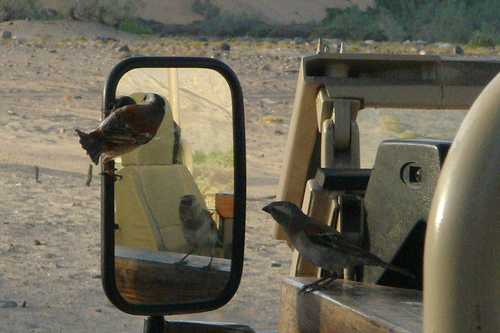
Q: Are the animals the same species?
A: Yes, all the animals are birds.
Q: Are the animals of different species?
A: No, all the animals are birds.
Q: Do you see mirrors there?
A: Yes, there is a mirror.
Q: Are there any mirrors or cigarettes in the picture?
A: Yes, there is a mirror.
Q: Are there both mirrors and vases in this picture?
A: No, there is a mirror but no vases.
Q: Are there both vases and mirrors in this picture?
A: No, there is a mirror but no vases.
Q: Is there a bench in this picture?
A: No, there are no benches.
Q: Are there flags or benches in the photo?
A: No, there are no benches or flags.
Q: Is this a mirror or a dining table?
A: This is a mirror.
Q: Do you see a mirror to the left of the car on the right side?
A: Yes, there is a mirror to the left of the car.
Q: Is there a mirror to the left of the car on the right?
A: Yes, there is a mirror to the left of the car.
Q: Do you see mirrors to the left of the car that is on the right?
A: Yes, there is a mirror to the left of the car.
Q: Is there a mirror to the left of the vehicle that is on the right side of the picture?
A: Yes, there is a mirror to the left of the car.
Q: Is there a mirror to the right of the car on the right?
A: No, the mirror is to the left of the car.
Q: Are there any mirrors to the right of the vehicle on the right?
A: No, the mirror is to the left of the car.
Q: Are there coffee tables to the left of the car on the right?
A: No, there is a mirror to the left of the car.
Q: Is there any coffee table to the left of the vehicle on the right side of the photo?
A: No, there is a mirror to the left of the car.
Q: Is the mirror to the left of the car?
A: Yes, the mirror is to the left of the car.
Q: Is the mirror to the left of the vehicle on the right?
A: Yes, the mirror is to the left of the car.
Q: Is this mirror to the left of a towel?
A: No, the mirror is to the left of the car.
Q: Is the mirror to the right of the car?
A: No, the mirror is to the left of the car.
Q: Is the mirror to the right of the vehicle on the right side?
A: No, the mirror is to the left of the car.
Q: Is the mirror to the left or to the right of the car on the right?
A: The mirror is to the left of the car.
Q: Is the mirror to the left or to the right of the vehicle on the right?
A: The mirror is to the left of the car.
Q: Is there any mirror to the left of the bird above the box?
A: Yes, there is a mirror to the left of the bird.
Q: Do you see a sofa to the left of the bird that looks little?
A: No, there is a mirror to the left of the bird.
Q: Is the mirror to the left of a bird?
A: Yes, the mirror is to the left of a bird.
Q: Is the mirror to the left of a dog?
A: No, the mirror is to the left of a bird.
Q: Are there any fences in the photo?
A: No, there are no fences.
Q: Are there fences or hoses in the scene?
A: No, there are no fences or hoses.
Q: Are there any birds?
A: Yes, there is a bird.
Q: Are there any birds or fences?
A: Yes, there is a bird.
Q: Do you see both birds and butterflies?
A: No, there is a bird but no butterflies.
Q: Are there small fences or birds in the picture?
A: Yes, there is a small bird.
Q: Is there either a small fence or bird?
A: Yes, there is a small bird.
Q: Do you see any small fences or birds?
A: Yes, there is a small bird.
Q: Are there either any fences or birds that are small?
A: Yes, the bird is small.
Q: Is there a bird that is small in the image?
A: Yes, there is a small bird.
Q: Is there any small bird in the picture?
A: Yes, there is a small bird.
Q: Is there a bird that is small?
A: Yes, there is a bird that is small.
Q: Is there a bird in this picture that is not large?
A: Yes, there is a small bird.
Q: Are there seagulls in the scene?
A: No, there are no seagulls.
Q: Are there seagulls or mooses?
A: No, there are no seagulls or mooses.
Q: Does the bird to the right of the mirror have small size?
A: Yes, the bird is small.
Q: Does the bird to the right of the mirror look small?
A: Yes, the bird is small.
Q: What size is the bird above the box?
A: The bird is small.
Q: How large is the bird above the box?
A: The bird is small.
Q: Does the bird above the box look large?
A: No, the bird is small.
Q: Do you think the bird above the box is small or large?
A: The bird is small.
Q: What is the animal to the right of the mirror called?
A: The animal is a bird.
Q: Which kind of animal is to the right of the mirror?
A: The animal is a bird.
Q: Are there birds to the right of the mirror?
A: Yes, there is a bird to the right of the mirror.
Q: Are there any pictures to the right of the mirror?
A: No, there is a bird to the right of the mirror.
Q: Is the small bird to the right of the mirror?
A: Yes, the bird is to the right of the mirror.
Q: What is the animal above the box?
A: The animal is a bird.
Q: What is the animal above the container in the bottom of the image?
A: The animal is a bird.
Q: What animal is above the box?
A: The animal is a bird.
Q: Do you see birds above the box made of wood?
A: Yes, there is a bird above the box.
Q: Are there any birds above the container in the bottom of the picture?
A: Yes, there is a bird above the box.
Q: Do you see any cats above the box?
A: No, there is a bird above the box.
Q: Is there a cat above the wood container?
A: No, there is a bird above the box.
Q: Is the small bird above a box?
A: Yes, the bird is above a box.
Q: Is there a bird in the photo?
A: Yes, there is a bird.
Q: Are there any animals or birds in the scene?
A: Yes, there is a bird.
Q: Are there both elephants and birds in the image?
A: No, there is a bird but no elephants.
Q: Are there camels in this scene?
A: No, there are no camels.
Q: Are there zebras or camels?
A: No, there are no camels or zebras.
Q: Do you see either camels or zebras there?
A: No, there are no camels or zebras.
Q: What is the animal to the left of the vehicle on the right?
A: The animal is a bird.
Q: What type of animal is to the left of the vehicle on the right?
A: The animal is a bird.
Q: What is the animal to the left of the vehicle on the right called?
A: The animal is a bird.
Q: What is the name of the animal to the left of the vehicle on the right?
A: The animal is a bird.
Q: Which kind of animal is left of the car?
A: The animal is a bird.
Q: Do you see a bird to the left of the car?
A: Yes, there is a bird to the left of the car.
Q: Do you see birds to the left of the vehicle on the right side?
A: Yes, there is a bird to the left of the car.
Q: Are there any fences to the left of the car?
A: No, there is a bird to the left of the car.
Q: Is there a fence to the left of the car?
A: No, there is a bird to the left of the car.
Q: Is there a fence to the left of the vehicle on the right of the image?
A: No, there is a bird to the left of the car.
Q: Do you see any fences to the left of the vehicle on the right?
A: No, there is a bird to the left of the car.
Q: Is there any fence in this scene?
A: No, there are no fences.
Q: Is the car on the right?
A: Yes, the car is on the right of the image.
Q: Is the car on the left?
A: No, the car is on the right of the image.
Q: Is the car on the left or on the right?
A: The car is on the right of the image.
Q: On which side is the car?
A: The car is on the right of the image.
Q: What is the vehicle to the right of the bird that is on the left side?
A: The vehicle is a car.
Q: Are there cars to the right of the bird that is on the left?
A: Yes, there is a car to the right of the bird.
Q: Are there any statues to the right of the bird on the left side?
A: No, there is a car to the right of the bird.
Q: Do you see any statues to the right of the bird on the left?
A: No, there is a car to the right of the bird.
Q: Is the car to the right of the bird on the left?
A: Yes, the car is to the right of the bird.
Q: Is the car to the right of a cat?
A: No, the car is to the right of the bird.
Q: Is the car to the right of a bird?
A: Yes, the car is to the right of a bird.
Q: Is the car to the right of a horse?
A: No, the car is to the right of a bird.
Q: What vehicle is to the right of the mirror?
A: The vehicle is a car.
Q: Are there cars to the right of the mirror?
A: Yes, there is a car to the right of the mirror.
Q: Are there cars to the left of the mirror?
A: No, the car is to the right of the mirror.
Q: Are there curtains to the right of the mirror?
A: No, there is a car to the right of the mirror.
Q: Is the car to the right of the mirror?
A: Yes, the car is to the right of the mirror.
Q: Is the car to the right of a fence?
A: No, the car is to the right of the mirror.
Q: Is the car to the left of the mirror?
A: No, the car is to the right of the mirror.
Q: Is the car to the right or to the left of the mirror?
A: The car is to the right of the mirror.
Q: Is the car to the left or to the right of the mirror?
A: The car is to the right of the mirror.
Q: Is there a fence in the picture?
A: No, there are no fences.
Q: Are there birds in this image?
A: Yes, there is a bird.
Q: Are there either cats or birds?
A: Yes, there is a bird.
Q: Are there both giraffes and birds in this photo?
A: No, there is a bird but no giraffes.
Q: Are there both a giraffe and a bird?
A: No, there is a bird but no giraffes.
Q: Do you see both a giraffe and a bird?
A: No, there is a bird but no giraffes.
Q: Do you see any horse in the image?
A: No, there are no horses.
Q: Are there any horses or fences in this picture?
A: No, there are no horses or fences.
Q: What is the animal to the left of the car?
A: The animal is a bird.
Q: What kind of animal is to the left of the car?
A: The animal is a bird.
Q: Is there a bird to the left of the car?
A: Yes, there is a bird to the left of the car.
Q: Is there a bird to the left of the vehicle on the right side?
A: Yes, there is a bird to the left of the car.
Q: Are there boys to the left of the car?
A: No, there is a bird to the left of the car.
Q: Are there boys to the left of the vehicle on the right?
A: No, there is a bird to the left of the car.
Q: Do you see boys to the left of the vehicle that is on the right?
A: No, there is a bird to the left of the car.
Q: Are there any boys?
A: No, there are no boys.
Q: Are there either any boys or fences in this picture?
A: No, there are no boys or fences.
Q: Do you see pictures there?
A: No, there are no pictures.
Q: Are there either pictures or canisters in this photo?
A: No, there are no pictures or canisters.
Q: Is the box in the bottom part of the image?
A: Yes, the box is in the bottom of the image.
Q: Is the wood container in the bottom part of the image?
A: Yes, the box is in the bottom of the image.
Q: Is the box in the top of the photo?
A: No, the box is in the bottom of the image.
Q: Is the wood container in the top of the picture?
A: No, the box is in the bottom of the image.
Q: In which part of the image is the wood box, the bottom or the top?
A: The box is in the bottom of the image.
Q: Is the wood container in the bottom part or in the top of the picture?
A: The box is in the bottom of the image.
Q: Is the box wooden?
A: Yes, the box is wooden.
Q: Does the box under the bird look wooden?
A: Yes, the box is wooden.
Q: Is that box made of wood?
A: Yes, the box is made of wood.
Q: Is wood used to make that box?
A: Yes, the box is made of wood.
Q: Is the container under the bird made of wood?
A: Yes, the box is made of wood.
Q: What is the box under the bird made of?
A: The box is made of wood.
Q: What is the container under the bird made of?
A: The box is made of wood.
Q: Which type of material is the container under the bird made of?
A: The box is made of wood.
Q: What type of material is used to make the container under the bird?
A: The box is made of wood.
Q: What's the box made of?
A: The box is made of wood.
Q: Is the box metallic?
A: No, the box is wooden.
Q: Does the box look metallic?
A: No, the box is wooden.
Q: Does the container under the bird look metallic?
A: No, the box is wooden.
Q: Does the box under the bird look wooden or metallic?
A: The box is wooden.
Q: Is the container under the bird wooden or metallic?
A: The box is wooden.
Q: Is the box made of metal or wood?
A: The box is made of wood.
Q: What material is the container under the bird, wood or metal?
A: The box is made of wood.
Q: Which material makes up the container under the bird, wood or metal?
A: The box is made of wood.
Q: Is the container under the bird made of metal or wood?
A: The box is made of wood.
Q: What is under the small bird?
A: The box is under the bird.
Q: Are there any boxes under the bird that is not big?
A: Yes, there is a box under the bird.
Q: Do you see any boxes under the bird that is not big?
A: Yes, there is a box under the bird.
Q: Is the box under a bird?
A: Yes, the box is under a bird.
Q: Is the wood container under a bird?
A: Yes, the box is under a bird.